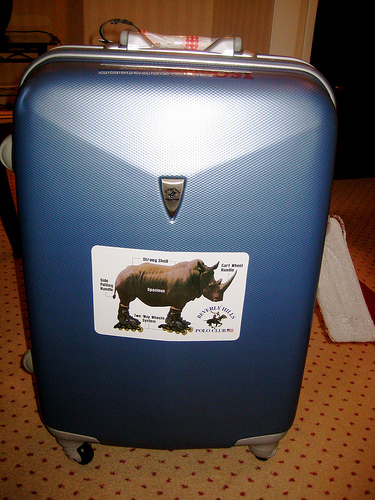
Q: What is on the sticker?
A: A rhino.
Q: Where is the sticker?
A: Suitcase.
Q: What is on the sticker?
A: A rhino.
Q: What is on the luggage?
A: A sticker.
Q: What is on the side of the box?
A: Cloth.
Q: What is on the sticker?
A: A animal.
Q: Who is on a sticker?
A: A rhino.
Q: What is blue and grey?
A: A suitcase.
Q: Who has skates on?
A: A rhino.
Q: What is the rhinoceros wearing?
A: It's wearing rollerblades.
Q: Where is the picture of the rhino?
A: On one side of the suitcase.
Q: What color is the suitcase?
A: Blue.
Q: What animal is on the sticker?
A: A rhinoceros.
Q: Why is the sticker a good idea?
A: It makes the suitcase easy to identify.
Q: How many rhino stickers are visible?
A: One.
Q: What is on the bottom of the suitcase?
A: Wheels.